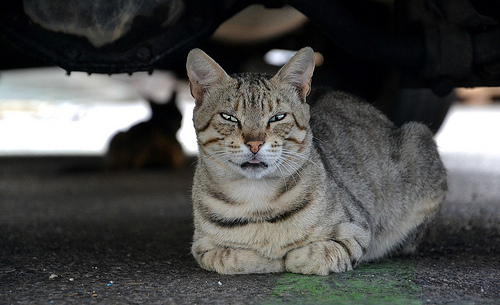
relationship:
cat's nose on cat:
[245, 140, 263, 153] [181, 45, 451, 275]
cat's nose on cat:
[245, 140, 263, 153] [246, 130, 271, 156]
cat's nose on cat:
[245, 140, 263, 153] [188, 49, 474, 283]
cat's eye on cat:
[268, 112, 286, 122] [181, 45, 451, 275]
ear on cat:
[187, 48, 233, 97] [181, 45, 451, 275]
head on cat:
[182, 44, 313, 178] [181, 45, 451, 275]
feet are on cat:
[185, 238, 360, 278] [167, 65, 454, 291]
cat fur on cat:
[185, 44, 450, 273] [181, 45, 451, 275]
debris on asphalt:
[35, 264, 118, 291] [18, 244, 157, 301]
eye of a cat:
[219, 109, 239, 124] [181, 45, 451, 275]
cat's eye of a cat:
[268, 112, 286, 122] [181, 45, 451, 275]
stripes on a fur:
[192, 193, 292, 237] [208, 196, 295, 224]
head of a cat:
[182, 44, 313, 178] [181, 45, 451, 275]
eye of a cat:
[220, 113, 239, 123] [181, 45, 451, 275]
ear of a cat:
[273, 42, 319, 103] [181, 45, 451, 275]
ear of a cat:
[183, 44, 236, 105] [181, 45, 451, 275]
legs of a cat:
[200, 227, 373, 282] [170, 34, 457, 279]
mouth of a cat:
[226, 140, 286, 175] [181, 45, 451, 275]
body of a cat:
[129, 22, 467, 272] [123, 37, 480, 283]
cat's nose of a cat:
[245, 140, 263, 153] [181, 45, 451, 275]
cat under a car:
[172, 49, 456, 266] [7, 4, 499, 131]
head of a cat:
[143, 86, 185, 129] [100, 89, 187, 166]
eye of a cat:
[220, 113, 239, 123] [202, 61, 337, 217]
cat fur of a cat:
[185, 44, 450, 273] [142, 40, 465, 283]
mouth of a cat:
[238, 161, 268, 173] [181, 45, 451, 275]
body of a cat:
[184, 47, 447, 275] [189, 72, 429, 228]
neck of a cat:
[202, 169, 322, 209] [181, 45, 451, 275]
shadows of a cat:
[437, 216, 479, 288] [100, 38, 457, 292]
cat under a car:
[107, 88, 185, 168] [1, 0, 498, 90]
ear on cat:
[271, 45, 316, 103] [181, 45, 451, 275]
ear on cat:
[167, 86, 180, 103] [98, 86, 188, 162]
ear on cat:
[140, 91, 159, 110] [98, 86, 188, 162]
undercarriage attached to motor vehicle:
[3, 4, 424, 52] [1, 4, 496, 137]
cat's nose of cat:
[245, 140, 263, 153] [181, 45, 451, 275]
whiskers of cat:
[264, 145, 323, 186] [181, 45, 451, 275]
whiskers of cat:
[193, 145, 246, 173] [181, 45, 451, 275]